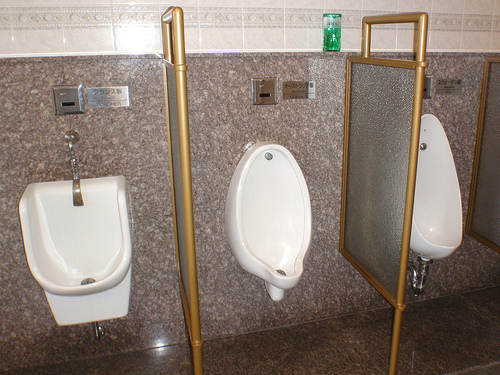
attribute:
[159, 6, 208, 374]
divider — gold, yellow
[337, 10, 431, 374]
divider — gold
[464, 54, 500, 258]
divider — gold, yellow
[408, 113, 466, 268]
urinal — white, indoors, clean, long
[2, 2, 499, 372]
wall — granite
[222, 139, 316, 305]
urinal — white, indoors, round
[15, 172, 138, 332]
urinal — white, square, clean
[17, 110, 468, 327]
three urinals — different, white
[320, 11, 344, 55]
air freshener — green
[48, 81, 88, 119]
mechanism — automatic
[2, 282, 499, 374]
floor — granite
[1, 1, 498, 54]
tile — designed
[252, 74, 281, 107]
mechanism — automatic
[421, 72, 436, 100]
mechanism — automatic